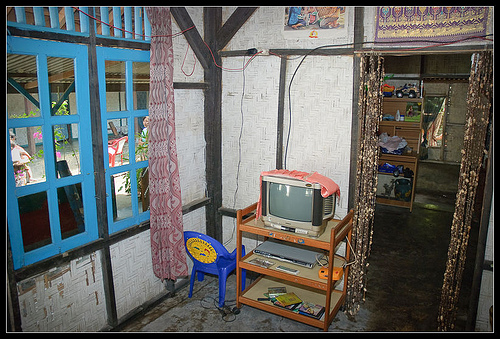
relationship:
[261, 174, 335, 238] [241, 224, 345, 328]
television on stand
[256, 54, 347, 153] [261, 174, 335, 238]
wall near television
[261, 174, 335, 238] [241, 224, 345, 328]
television in stand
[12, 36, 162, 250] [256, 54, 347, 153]
window near wall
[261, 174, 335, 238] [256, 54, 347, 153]
television near wall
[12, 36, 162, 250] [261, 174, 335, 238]
window near television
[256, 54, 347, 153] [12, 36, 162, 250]
wall near window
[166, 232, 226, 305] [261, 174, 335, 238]
chair near television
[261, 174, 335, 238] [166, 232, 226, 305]
television above chair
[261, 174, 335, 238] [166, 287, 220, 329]
television near floor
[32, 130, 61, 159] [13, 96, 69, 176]
flowers on plant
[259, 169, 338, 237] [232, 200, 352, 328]
television on stand